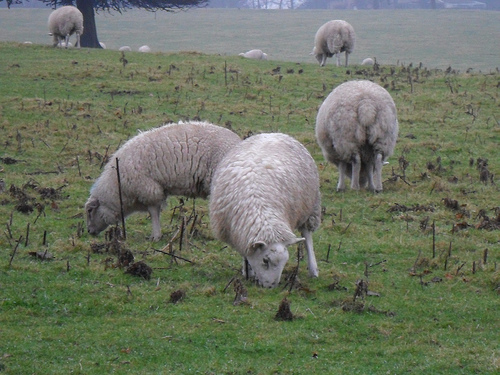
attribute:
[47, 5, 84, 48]
sheep — grazing, standing, feeding, white, wooly, walking, facing down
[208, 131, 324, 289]
sheep — grazing, curly, feeding, white, wooly, walking, facing down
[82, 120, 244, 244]
sheep — grazing, wooly, dirty, white, feeding, walking, facing down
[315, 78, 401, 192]
sheep — grazing, feeding, walking, white, facing down, wooly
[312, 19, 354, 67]
sheep — grazing, eating, feeding, walking, white, facing down, wooly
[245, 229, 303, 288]
head — bent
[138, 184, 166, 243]
leg — bare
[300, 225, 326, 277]
leg — bare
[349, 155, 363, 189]
leg — bare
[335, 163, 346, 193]
leg — bare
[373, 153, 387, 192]
leg — bare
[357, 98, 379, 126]
tail — flat, furry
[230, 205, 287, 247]
neck — curved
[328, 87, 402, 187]
back — wooly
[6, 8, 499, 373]
ground — large, green, cloudy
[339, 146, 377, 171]
underside — dark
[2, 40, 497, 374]
grass — green, trimmed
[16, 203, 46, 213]
plant — weed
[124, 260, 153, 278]
plant — weed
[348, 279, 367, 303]
plant — weed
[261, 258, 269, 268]
eye — black